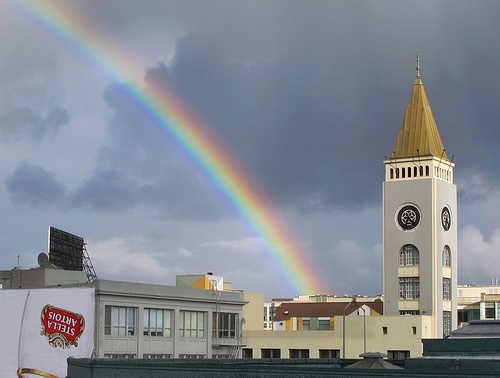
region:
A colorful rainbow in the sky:
[16, 0, 328, 296]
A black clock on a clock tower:
[392, 201, 417, 231]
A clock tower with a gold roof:
[380, 51, 456, 336]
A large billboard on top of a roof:
[42, 225, 94, 280]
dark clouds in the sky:
[180, 31, 360, 108]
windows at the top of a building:
[100, 300, 240, 345]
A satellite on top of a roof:
[32, 250, 47, 265]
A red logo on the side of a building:
[37, 300, 84, 350]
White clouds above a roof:
[100, 240, 167, 276]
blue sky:
[50, 147, 82, 167]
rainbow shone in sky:
[93, 53, 363, 277]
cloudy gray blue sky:
[187, 30, 330, 108]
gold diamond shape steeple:
[366, 64, 475, 163]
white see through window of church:
[370, 160, 479, 181]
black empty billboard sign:
[33, 218, 109, 286]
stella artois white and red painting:
[35, 296, 124, 367]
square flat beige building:
[256, 301, 432, 362]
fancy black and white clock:
[390, 193, 427, 240]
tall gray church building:
[379, 178, 489, 358]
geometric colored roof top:
[159, 268, 237, 302]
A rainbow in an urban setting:
[24, 18, 474, 353]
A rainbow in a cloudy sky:
[37, 12, 337, 222]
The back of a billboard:
[37, 221, 89, 273]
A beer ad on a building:
[10, 286, 87, 375]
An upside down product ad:
[31, 294, 87, 351]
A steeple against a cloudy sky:
[366, 26, 468, 294]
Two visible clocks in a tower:
[391, 196, 456, 236]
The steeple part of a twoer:
[377, 41, 457, 171]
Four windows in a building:
[98, 297, 250, 348]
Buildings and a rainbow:
[267, 262, 336, 318]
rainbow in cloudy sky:
[89, 48, 274, 225]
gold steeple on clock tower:
[374, 68, 456, 169]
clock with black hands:
[390, 197, 425, 234]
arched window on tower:
[395, 238, 423, 308]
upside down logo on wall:
[27, 298, 90, 352]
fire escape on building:
[218, 338, 248, 361]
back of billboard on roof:
[42, 222, 107, 284]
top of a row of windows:
[239, 346, 347, 359]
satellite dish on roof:
[34, 249, 54, 273]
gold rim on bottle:
[13, 363, 58, 375]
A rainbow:
[5, 0, 342, 292]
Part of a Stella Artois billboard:
[16, 282, 102, 377]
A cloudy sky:
[166, 0, 498, 227]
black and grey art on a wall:
[392, 188, 426, 237]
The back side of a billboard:
[37, 222, 100, 283]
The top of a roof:
[67, 341, 488, 376]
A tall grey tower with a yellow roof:
[373, 40, 474, 345]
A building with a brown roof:
[265, 292, 385, 330]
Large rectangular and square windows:
[102, 297, 139, 348]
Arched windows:
[393, 235, 425, 307]